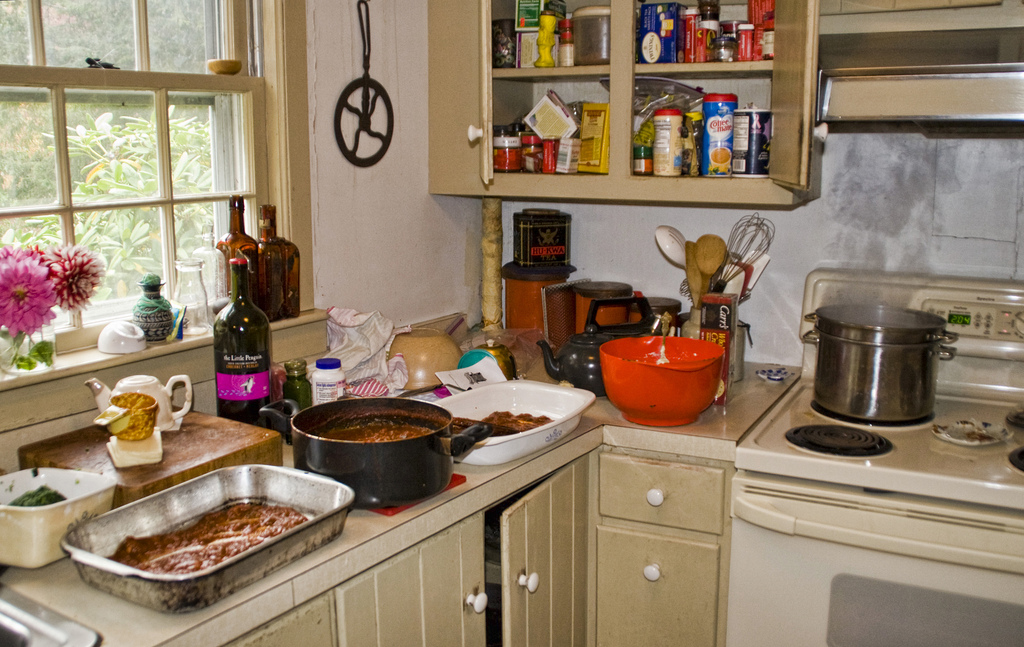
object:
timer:
[98, 321, 148, 354]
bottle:
[214, 258, 272, 430]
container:
[731, 109, 770, 178]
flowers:
[0, 246, 106, 337]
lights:
[1004, 313, 1010, 333]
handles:
[644, 488, 664, 581]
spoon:
[655, 225, 687, 270]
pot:
[536, 325, 615, 397]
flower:
[2, 246, 59, 337]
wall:
[306, 0, 482, 335]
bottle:
[310, 358, 345, 408]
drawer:
[599, 452, 725, 537]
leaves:
[0, 105, 213, 304]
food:
[104, 503, 307, 576]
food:
[258, 397, 491, 509]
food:
[451, 411, 557, 435]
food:
[8, 483, 66, 507]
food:
[298, 415, 437, 443]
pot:
[258, 396, 491, 509]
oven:
[728, 267, 1024, 646]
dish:
[60, 463, 356, 614]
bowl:
[600, 336, 726, 427]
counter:
[0, 362, 803, 643]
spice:
[654, 109, 684, 177]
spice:
[737, 24, 754, 61]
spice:
[544, 137, 558, 174]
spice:
[521, 136, 543, 172]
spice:
[534, 11, 558, 67]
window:
[0, 64, 331, 390]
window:
[0, 0, 263, 78]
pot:
[803, 304, 959, 427]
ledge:
[0, 308, 331, 475]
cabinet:
[429, 1, 823, 206]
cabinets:
[767, 148, 792, 184]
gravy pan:
[60, 463, 356, 614]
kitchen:
[0, 0, 1024, 647]